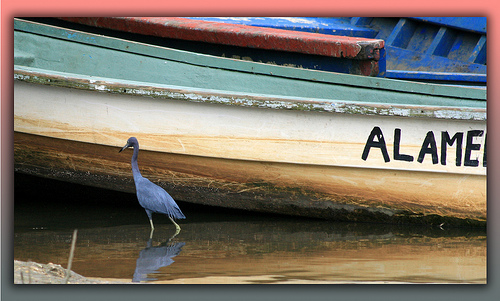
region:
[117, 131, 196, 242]
bird in the water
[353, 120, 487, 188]
name on a boat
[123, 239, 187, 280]
shadow of a bird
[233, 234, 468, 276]
water under a boat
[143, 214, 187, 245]
legs of a bird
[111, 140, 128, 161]
beak of a bird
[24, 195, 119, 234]
shadow under a boat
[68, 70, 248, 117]
chipped paint on side of boat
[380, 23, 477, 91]
blue side of a boat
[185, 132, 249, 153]
water stain on a boat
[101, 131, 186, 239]
bird in the photo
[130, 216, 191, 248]
legs of the bird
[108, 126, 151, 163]
head of the bird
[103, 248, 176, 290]
reflection of the bird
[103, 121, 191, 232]
gray bird on the ground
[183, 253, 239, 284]
water next to bird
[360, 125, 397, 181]
the letter A on the boat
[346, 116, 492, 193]
black word on the boat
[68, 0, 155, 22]
purple border of the photo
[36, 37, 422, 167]
boat next to the bird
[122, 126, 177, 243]
grey stork walking in water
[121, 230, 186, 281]
reflection of stork in water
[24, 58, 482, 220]
large white wooden boat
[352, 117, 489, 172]
name of boat painted in black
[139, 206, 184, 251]
two tall legs of grey stork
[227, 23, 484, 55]
blue and red structure behind white boat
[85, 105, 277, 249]
only one stork in water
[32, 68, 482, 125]
paint peeling off of boat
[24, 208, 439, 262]
reflection of boat in water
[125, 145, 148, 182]
long neck of stork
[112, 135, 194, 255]
Bird walking in the water.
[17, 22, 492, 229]
Canoe in the water.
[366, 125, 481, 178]
Writing on the side of the canoe.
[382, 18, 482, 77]
Blue boat in the back.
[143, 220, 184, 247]
Crane's feet in the water.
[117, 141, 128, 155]
The bird's beak on its face.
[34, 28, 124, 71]
Green paint on the canoe.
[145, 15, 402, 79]
Rust on the metal boat.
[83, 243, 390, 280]
Water in the river.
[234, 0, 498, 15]
Red frame around photo.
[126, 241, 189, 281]
reflection of bird in the water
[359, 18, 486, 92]
blue edge of a boat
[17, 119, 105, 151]
rust of a boat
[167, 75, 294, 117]
crackled paint on a boat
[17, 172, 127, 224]
shadow under a boat